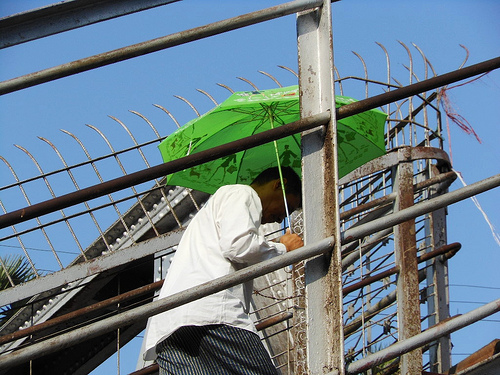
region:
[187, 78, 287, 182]
The umbrella is green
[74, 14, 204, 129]
The sky is blue and clear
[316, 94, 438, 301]
The poles are metal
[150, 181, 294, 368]
The man is wearing a white shirt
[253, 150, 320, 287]
The man is holding an umbrella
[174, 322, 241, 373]
The man's pants are striped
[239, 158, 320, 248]
The man has dark hair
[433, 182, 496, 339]
Power lines are visible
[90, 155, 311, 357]
The man is walking up stairs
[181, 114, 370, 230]
The umbrella has characters on it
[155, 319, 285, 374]
Black and white striped pants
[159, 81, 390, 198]
A man with a green umbrella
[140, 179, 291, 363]
A man with a white coat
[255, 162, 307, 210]
A man with short black hair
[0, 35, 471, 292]
A row of metal spikes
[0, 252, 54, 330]
Leaves of palm trees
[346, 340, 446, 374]
Leaves of palm trees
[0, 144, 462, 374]
A rusted metal railing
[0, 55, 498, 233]
A rusty metal pole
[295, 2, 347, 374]
A vertical rusty bar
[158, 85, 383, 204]
Green canopy of an umbrella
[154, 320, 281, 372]
Striped pants on a man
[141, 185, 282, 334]
White shirt on a man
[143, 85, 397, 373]
A man with a green umbrella ascends stairs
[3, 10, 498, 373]
Diagonal pole railings parallel to each other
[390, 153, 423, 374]
A metal post holding metal poles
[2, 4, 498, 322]
A blue sky with no clouds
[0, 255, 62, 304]
Leaves of a palm tree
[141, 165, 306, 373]
A man in a white shirt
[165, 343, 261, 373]
Striped pattern on a man's clothes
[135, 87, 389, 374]
man walking up stairs with an umbrella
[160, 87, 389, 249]
a green umbrella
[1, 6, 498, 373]
metal railings to the man's right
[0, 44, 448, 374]
large metal fence with spiked top on man's left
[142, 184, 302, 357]
the man's long sleeved shirt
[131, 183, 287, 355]
the shirt is white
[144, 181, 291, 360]
the shirt is untucked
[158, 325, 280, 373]
the man's black and gray striped bottoms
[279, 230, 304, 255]
a right hand holding the umbrella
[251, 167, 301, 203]
short black hair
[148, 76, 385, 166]
green umbrella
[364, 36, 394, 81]
white clouds in blue sky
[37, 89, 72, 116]
white clouds in blue sky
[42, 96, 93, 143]
white clouds in blue sky